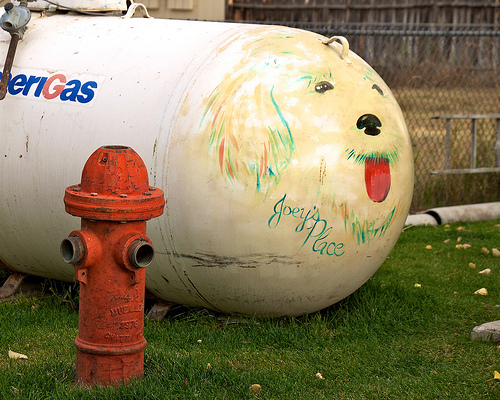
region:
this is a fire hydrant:
[54, 128, 183, 391]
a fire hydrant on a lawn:
[47, 128, 214, 395]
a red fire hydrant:
[42, 126, 205, 398]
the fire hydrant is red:
[16, 110, 204, 390]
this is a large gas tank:
[2, 5, 420, 334]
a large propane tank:
[1, 6, 428, 346]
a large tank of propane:
[2, 5, 428, 327]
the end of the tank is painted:
[161, 19, 461, 329]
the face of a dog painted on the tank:
[196, 26, 439, 334]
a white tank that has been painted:
[5, 0, 423, 326]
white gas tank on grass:
[0, 36, 379, 275]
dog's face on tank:
[212, 34, 405, 283]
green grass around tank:
[390, 274, 498, 392]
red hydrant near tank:
[49, 159, 156, 363]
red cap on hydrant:
[80, 145, 167, 215]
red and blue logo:
[4, 56, 120, 140]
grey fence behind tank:
[292, 8, 494, 211]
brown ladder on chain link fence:
[417, 112, 499, 188]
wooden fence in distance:
[200, 0, 499, 68]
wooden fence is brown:
[325, 13, 495, 76]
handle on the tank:
[123, 1, 149, 18]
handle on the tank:
[324, 28, 363, 61]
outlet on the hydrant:
[121, 236, 161, 273]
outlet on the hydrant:
[52, 226, 90, 263]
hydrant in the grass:
[57, 130, 164, 387]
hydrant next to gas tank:
[58, 134, 170, 393]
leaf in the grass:
[0, 338, 31, 359]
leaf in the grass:
[470, 277, 491, 302]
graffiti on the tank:
[238, 182, 349, 264]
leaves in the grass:
[453, 239, 473, 254]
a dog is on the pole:
[180, 13, 440, 295]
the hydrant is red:
[25, 130, 269, 383]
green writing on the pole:
[256, 180, 463, 346]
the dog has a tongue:
[317, 125, 457, 220]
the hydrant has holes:
[40, 211, 215, 342]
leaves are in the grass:
[175, 305, 295, 390]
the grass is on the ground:
[185, 331, 300, 386]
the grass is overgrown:
[160, 310, 285, 378]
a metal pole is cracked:
[403, 162, 488, 260]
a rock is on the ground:
[446, 308, 498, 347]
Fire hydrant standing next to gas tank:
[15, 3, 450, 376]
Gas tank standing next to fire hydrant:
[15, 5, 445, 387]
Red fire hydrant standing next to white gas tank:
[16, 10, 456, 385]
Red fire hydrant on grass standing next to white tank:
[25, 10, 470, 381]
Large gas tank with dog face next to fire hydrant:
[35, 10, 457, 390]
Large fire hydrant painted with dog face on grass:
[22, 2, 472, 382]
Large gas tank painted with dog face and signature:
[31, 5, 471, 385]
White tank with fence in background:
[35, 5, 465, 395]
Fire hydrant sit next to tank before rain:
[32, 5, 472, 390]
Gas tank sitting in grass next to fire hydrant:
[32, 5, 478, 391]